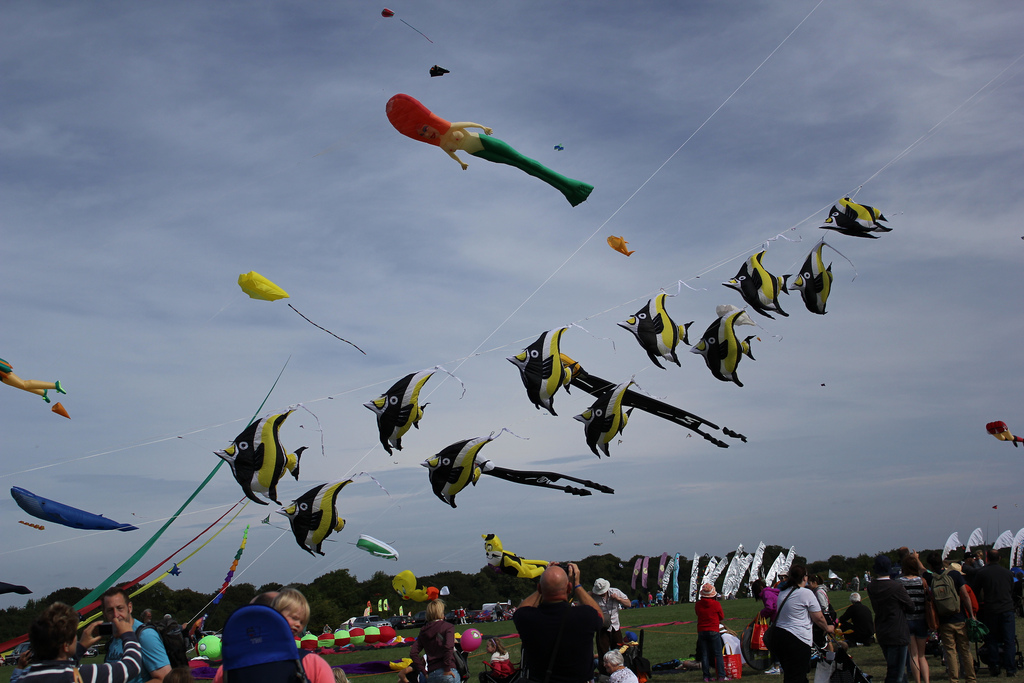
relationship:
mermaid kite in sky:
[384, 94, 590, 207] [2, 1, 1018, 581]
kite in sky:
[818, 182, 892, 247] [2, 1, 1018, 581]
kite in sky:
[231, 415, 314, 500] [2, 1, 1018, 581]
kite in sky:
[276, 472, 365, 559] [2, 1, 1018, 581]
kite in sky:
[365, 378, 439, 454] [2, 1, 1018, 581]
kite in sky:
[417, 426, 601, 522] [2, 1, 1018, 581]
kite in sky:
[507, 333, 747, 461] [2, 1, 1018, 581]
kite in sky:
[572, 381, 652, 455] [2, 1, 1018, 581]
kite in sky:
[619, 286, 713, 369] [2, 1, 1018, 581]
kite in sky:
[695, 303, 769, 397] [2, 1, 1018, 581]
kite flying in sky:
[236, 267, 373, 360] [2, 1, 1018, 581]